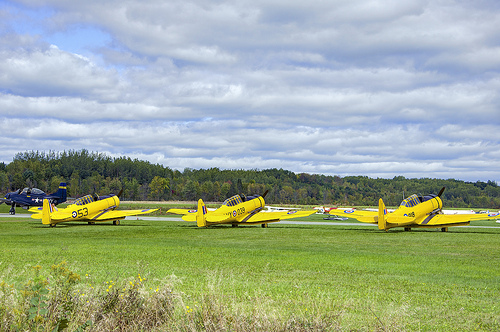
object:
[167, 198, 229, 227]
tail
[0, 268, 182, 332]
plants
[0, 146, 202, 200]
forest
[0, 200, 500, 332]
field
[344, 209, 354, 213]
sticker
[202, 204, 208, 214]
symbol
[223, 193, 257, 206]
cockpit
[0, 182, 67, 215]
airplane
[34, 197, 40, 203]
star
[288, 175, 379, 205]
trees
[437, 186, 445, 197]
propeller blade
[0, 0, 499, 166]
sky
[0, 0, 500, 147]
clouds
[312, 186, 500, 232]
airplane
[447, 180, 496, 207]
trees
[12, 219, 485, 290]
lawn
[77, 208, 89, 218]
number 53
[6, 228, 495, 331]
grass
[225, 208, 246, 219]
number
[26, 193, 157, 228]
airplane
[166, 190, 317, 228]
airplane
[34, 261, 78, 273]
flowers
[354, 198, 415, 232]
tail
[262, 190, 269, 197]
propeller